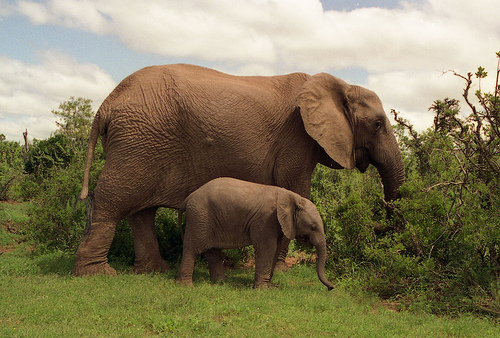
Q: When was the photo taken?
A: Day time.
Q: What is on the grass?
A: Elephants.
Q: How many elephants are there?
A: Two.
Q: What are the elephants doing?
A: Standing.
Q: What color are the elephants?
A: Brown.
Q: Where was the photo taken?
A: Wildlife park.